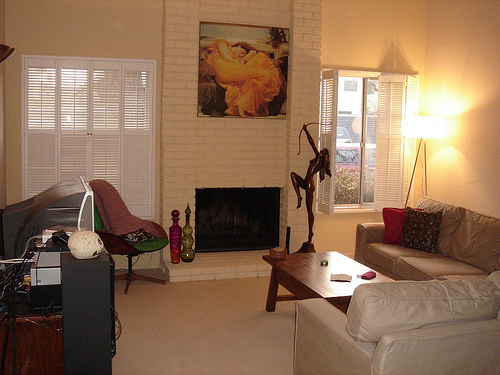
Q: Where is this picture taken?
A: Inside a home.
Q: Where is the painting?
A: Above the fireplace.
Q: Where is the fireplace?
A: Below the painting.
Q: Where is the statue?
A: To the right of the fireplace.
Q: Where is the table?
A: In front of the sofa.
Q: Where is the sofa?
A: Against the wall.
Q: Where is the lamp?
A: In the corner.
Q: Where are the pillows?
A: On the sofa.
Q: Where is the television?
A: On the left side of the picture.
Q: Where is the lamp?
A: In the corner.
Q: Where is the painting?
A: Above the fireplace.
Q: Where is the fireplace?
A: Below the painting.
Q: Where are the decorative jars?
A: Beside the fireplace.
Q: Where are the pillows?
A: On the sofa.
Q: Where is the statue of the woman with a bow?
A: By the fireplace.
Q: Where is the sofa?
A: Against the wall.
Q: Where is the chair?
A: Beside the fireplace.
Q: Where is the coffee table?
A: In the center of the room.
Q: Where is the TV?
A: On the left side of the picture.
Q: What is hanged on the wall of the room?
A: Large painting of woman.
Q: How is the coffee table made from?
A: Brown wood.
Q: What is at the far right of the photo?
A: Window with open shutters.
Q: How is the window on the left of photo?
A: It has closed shutters.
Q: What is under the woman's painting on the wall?
A: Fireplace without fire.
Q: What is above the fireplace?
A: A painting.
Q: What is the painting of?
A: A woman.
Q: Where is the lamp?
A: In the corner.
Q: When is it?
A: Day time.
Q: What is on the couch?
A: Pillows.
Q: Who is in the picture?
A: No one.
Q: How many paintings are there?
A: One.